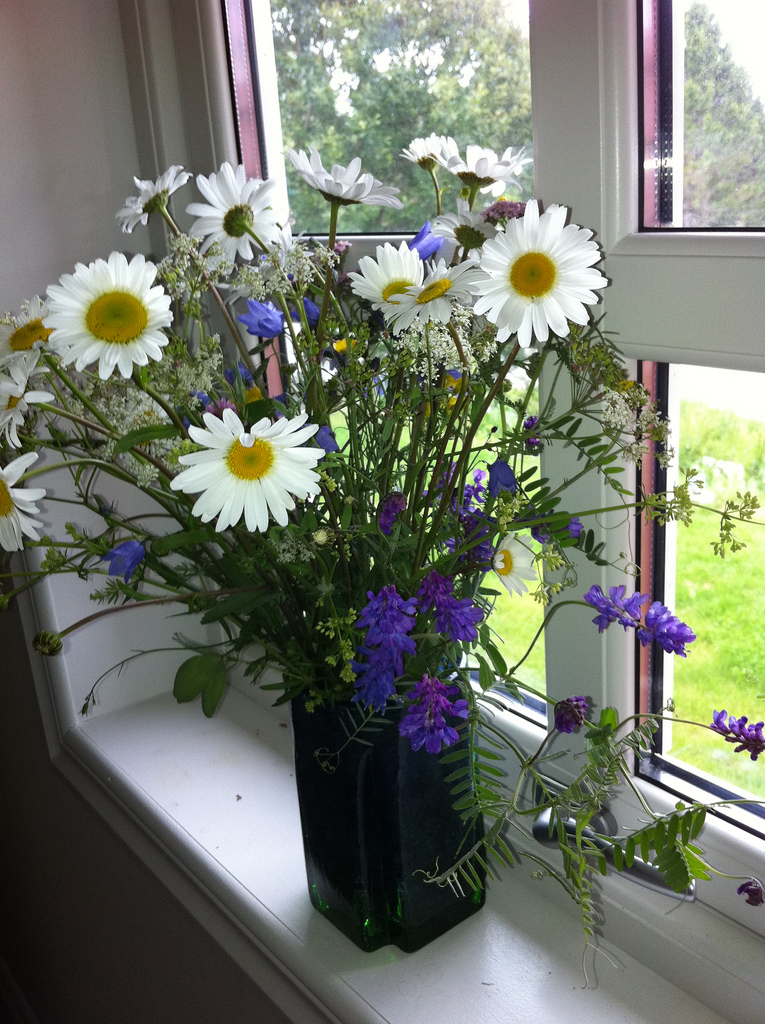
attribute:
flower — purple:
[352, 590, 426, 711]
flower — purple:
[399, 668, 471, 757]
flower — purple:
[419, 574, 484, 638]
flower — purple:
[579, 580, 695, 660]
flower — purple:
[549, 694, 593, 731]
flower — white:
[349, 237, 429, 312]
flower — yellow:
[507, 248, 559, 300]